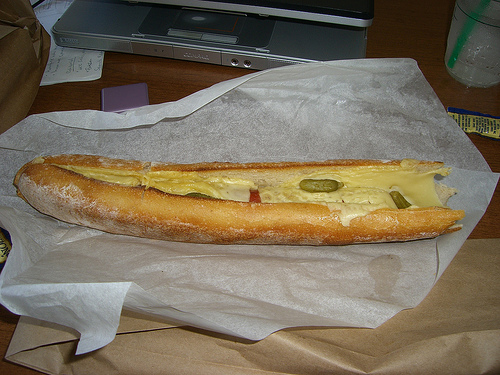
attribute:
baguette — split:
[12, 149, 466, 247]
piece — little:
[101, 81, 153, 110]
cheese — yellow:
[338, 166, 425, 201]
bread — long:
[11, 150, 466, 247]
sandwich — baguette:
[3, 151, 461, 234]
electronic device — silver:
[53, 2, 370, 82]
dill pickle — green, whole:
[275, 175, 344, 199]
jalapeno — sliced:
[295, 175, 345, 213]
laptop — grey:
[173, 32, 250, 69]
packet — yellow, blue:
[443, 111, 496, 141]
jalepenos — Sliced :
[286, 177, 348, 204]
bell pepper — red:
[235, 190, 266, 208]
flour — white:
[30, 189, 39, 199]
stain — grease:
[369, 247, 409, 307]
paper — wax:
[21, 245, 325, 310]